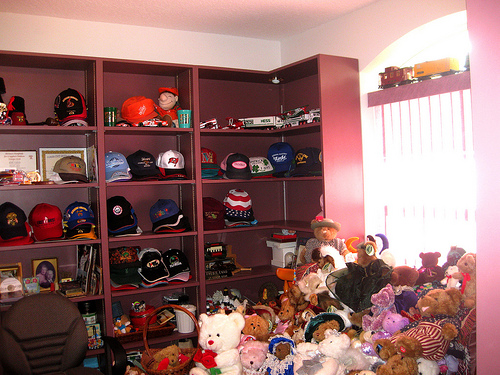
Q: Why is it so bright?
A: Sunlight.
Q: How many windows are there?
A: One.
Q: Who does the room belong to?
A: A woman.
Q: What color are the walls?
A: Pink.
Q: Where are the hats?
A: The shelves.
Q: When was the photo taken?
A: Day time.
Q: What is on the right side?
A: Stuffed animals.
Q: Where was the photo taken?
A: A room.